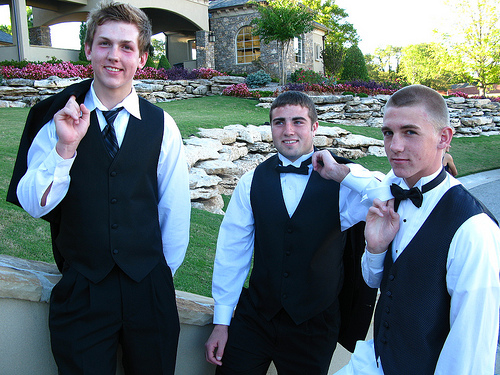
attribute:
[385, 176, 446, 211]
bow — black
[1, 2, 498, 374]
boys — young, dressed up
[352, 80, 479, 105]
flowers — red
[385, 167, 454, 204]
bow tie — black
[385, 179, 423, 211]
bow tie — black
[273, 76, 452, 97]
flowers — red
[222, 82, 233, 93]
flower — red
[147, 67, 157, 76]
flower — red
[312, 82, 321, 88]
flower —  red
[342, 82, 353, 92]
flower —  red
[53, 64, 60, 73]
flower —  red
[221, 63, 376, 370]
vest — black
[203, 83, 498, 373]
boys — young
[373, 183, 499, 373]
vest — black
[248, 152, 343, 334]
vest — black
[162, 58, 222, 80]
flowers — red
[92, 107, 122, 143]
tie — striped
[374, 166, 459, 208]
tie — black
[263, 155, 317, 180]
tie — black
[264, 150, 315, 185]
bowtie — black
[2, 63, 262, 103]
flowers — red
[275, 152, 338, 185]
tie — black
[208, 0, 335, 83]
house — small, stone, walled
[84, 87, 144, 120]
collar — white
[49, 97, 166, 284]
vest — black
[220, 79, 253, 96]
flowers — red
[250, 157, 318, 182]
bow tie — black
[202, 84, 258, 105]
flowers — red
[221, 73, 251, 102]
flowers —  red